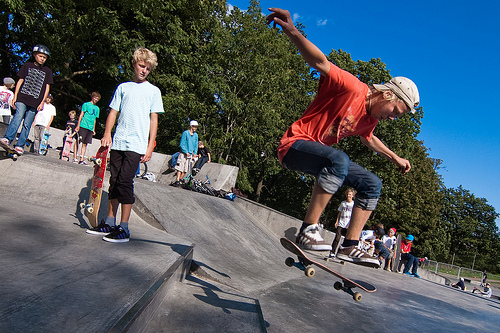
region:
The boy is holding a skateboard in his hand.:
[88, 47, 175, 249]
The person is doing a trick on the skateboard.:
[295, 32, 417, 302]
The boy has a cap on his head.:
[371, 64, 434, 117]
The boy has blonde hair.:
[124, 37, 170, 64]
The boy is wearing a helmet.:
[29, 38, 54, 60]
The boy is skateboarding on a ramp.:
[153, 28, 392, 280]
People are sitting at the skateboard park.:
[381, 225, 421, 278]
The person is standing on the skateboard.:
[11, 39, 59, 145]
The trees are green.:
[166, 13, 320, 153]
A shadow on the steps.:
[170, 233, 267, 330]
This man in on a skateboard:
[262, 3, 432, 310]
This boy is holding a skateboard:
[72, 36, 162, 246]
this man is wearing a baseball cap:
[363, 59, 438, 131]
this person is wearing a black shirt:
[14, 36, 56, 136]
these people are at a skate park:
[16, 30, 469, 327]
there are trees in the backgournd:
[60, 11, 322, 91]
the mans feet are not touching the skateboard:
[291, 222, 387, 276]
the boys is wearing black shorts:
[102, 141, 137, 215]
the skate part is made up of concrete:
[116, 232, 483, 326]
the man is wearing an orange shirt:
[312, 60, 377, 168]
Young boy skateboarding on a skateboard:
[265, 6, 425, 307]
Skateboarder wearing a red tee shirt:
[270, 25, 376, 150]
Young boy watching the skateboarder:
[82, 45, 162, 242]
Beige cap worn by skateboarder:
[372, 72, 422, 118]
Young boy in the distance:
[175, 118, 202, 190]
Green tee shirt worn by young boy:
[77, 99, 102, 131]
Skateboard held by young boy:
[78, 141, 109, 229]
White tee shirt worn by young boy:
[108, 77, 165, 156]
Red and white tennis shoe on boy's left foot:
[336, 245, 382, 269]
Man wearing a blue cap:
[403, 229, 416, 246]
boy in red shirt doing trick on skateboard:
[277, 74, 434, 298]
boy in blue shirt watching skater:
[77, 45, 166, 245]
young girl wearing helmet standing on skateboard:
[0, 42, 55, 163]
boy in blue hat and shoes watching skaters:
[403, 234, 420, 279]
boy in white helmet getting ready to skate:
[172, 118, 202, 187]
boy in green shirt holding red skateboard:
[61, 89, 104, 166]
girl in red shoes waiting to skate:
[5, 45, 52, 157]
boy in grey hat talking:
[0, 76, 21, 124]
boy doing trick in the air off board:
[279, 75, 419, 301]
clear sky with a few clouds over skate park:
[263, 4, 352, 44]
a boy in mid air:
[261, 3, 421, 268]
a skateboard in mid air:
[277, 233, 377, 302]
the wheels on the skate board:
[285, 258, 364, 302]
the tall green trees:
[2, 0, 499, 273]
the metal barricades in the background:
[418, 257, 487, 285]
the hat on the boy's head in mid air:
[371, 75, 419, 116]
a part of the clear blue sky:
[340, 0, 499, 232]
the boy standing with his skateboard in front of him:
[85, 47, 165, 242]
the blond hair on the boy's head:
[131, 46, 160, 69]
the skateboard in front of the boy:
[78, 141, 108, 229]